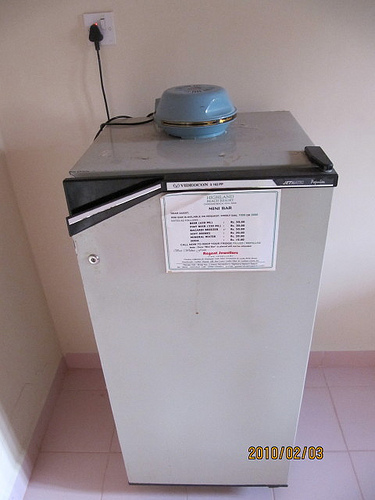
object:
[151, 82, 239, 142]
blue popcorn maker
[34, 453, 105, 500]
white square tile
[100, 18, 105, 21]
red button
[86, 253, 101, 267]
metal lock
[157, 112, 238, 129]
metal seal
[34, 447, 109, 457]
gray line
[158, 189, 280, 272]
paper on the fridge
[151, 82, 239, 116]
blue color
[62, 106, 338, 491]
fridge is black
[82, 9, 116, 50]
switch is fixed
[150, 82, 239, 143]
stabilizer on fridge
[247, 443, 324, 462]
yellow date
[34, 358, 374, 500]
white tile floor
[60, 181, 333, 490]
grey door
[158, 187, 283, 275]
sign on the door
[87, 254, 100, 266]
silver key hole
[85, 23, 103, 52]
black plug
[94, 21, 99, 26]
red indicator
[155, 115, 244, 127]
gold colored trim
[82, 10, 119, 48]
white outlet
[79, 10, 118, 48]
white switch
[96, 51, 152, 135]
electrical cord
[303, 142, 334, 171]
black fastener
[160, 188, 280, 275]
square logo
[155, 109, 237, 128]
silver base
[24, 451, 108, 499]
white tiles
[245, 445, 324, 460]
date in the picture.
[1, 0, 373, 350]
wall is white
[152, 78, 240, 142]
blue stabilizer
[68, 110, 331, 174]
top of the fridge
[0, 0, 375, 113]
wall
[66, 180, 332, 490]
door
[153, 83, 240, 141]
appliance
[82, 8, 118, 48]
electrical outlet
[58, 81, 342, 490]
refrigerator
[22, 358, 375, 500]
floor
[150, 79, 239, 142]
stabilizer